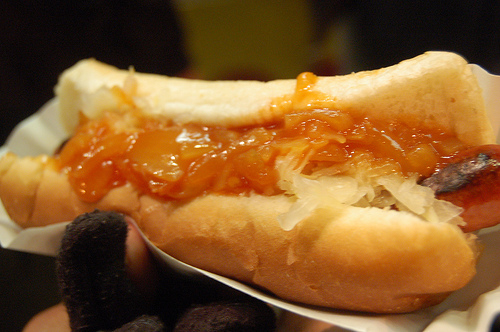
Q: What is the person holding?
A: Hot dog.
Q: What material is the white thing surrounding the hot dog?
A: Paper.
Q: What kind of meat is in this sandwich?
A: Hot dog.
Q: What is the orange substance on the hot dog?
A: Sauce.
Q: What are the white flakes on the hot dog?
A: Sauerkraut.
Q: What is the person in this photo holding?
A: Hot dog.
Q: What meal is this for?
A: Lunch.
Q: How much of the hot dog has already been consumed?
A: None.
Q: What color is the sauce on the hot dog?
A: Orange.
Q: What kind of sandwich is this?
A: Hot dog.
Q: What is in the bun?
A: Hot dog.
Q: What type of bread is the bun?
A: White.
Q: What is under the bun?
A: Napkin.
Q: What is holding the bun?
A: Hand with gloves on.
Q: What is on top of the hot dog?
A: Condiments.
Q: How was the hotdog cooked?
A: Grilled.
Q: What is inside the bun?
A: Hot Dog.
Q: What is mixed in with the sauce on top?
A: Onions.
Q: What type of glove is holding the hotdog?
A: Fuzzy.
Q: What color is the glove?
A: Black.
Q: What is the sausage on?
A: A bun.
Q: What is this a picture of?
A: A hot dog.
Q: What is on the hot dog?
A: Sauerkraut.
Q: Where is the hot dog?
A: In a bun.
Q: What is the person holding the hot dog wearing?
A: Gloves.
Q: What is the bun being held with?
A: A napkin.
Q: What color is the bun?
A: Brown.